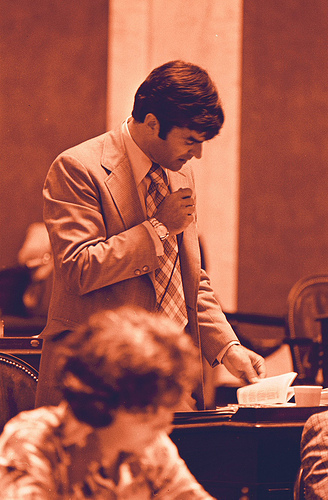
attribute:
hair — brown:
[127, 57, 226, 143]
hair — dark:
[130, 59, 224, 140]